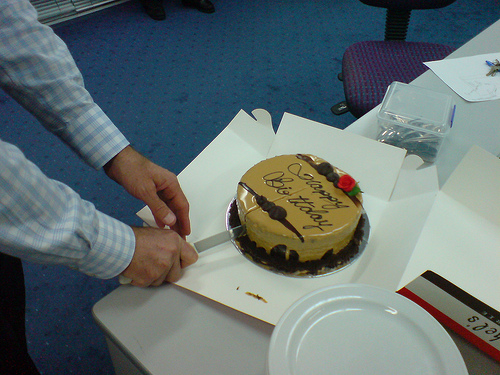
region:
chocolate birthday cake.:
[238, 148, 365, 273]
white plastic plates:
[254, 288, 475, 373]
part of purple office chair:
[330, 0, 447, 63]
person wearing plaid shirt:
[0, 0, 129, 281]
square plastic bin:
[368, 80, 454, 148]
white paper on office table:
[424, 47, 499, 97]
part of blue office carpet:
[126, 23, 269, 107]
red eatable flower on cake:
[334, 173, 357, 193]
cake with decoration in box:
[205, 135, 400, 290]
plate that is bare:
[259, 287, 487, 369]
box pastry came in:
[149, 99, 421, 308]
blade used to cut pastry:
[195, 230, 256, 245]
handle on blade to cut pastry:
[122, 246, 202, 278]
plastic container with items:
[364, 79, 466, 156]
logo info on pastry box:
[421, 280, 496, 335]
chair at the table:
[322, 0, 472, 124]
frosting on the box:
[234, 277, 270, 317]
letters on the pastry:
[256, 153, 345, 238]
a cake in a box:
[136, 95, 446, 340]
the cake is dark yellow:
[216, 142, 382, 284]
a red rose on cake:
[332, 166, 358, 197]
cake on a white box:
[132, 92, 450, 336]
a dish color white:
[253, 276, 473, 373]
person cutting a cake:
[1, 7, 374, 322]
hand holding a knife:
[108, 208, 245, 301]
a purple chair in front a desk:
[327, 1, 480, 111]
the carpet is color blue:
[71, 7, 366, 131]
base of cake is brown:
[219, 146, 379, 283]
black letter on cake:
[285, 158, 318, 185]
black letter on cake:
[306, 176, 322, 189]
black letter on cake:
[311, 185, 331, 200]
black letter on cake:
[316, 196, 339, 203]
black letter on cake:
[321, 197, 347, 212]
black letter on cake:
[304, 218, 334, 233]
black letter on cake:
[308, 209, 318, 221]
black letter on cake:
[298, 203, 327, 217]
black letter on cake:
[291, 200, 311, 207]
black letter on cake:
[262, 169, 289, 189]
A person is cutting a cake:
[0, 0, 372, 295]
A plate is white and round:
[260, 275, 476, 370]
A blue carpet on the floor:
[0, 0, 495, 370]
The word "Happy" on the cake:
[282, 155, 349, 215]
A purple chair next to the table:
[321, 0, 461, 125]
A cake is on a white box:
[125, 97, 496, 367]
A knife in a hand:
[107, 215, 252, 292]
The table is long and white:
[85, 12, 496, 369]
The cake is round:
[221, 142, 371, 282]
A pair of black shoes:
[135, 0, 221, 26]